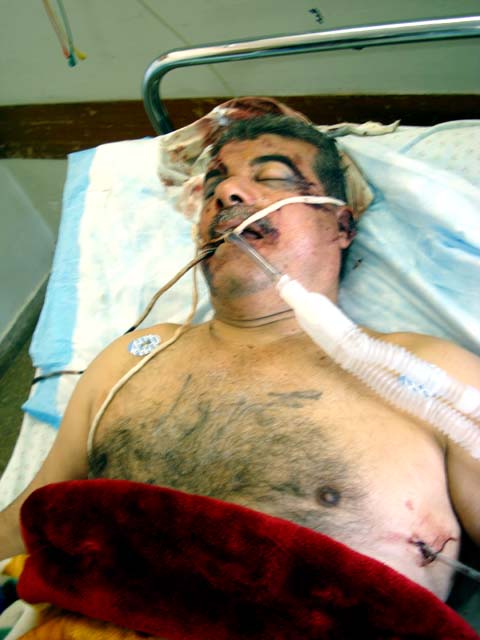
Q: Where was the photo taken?
A: In a hospital room.